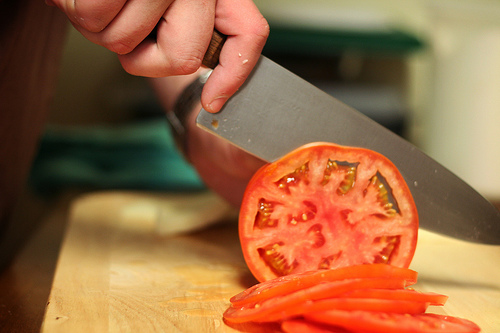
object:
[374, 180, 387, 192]
seed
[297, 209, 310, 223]
seed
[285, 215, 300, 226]
seed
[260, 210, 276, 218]
seed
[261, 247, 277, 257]
seed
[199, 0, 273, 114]
finger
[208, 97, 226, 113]
fingernail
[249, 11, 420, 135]
metal background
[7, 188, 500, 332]
board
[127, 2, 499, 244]
knife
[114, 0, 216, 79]
fingers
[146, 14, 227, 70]
handle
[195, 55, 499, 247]
blade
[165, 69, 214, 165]
band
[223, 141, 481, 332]
tomato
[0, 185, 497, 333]
counter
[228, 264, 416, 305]
slices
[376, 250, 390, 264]
seeds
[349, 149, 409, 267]
flesh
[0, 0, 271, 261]
person